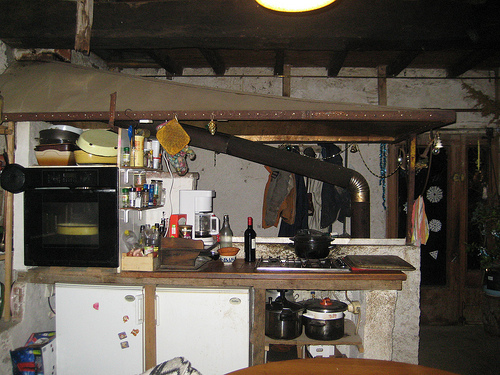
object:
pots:
[300, 313, 347, 341]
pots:
[74, 128, 118, 157]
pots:
[34, 143, 78, 167]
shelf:
[24, 122, 120, 267]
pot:
[287, 227, 335, 260]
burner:
[255, 254, 352, 274]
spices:
[121, 185, 133, 209]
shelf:
[120, 125, 165, 257]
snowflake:
[426, 185, 444, 203]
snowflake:
[428, 217, 442, 234]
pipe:
[114, 119, 370, 238]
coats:
[261, 145, 297, 230]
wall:
[159, 140, 386, 241]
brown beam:
[73, 0, 95, 55]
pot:
[193, 211, 220, 239]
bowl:
[219, 254, 237, 265]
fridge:
[54, 282, 144, 374]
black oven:
[23, 168, 118, 268]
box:
[167, 213, 187, 238]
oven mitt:
[155, 117, 192, 155]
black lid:
[288, 228, 335, 245]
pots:
[264, 294, 306, 340]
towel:
[409, 195, 430, 247]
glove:
[164, 142, 198, 177]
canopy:
[0, 56, 457, 142]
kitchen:
[0, 1, 492, 357]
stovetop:
[257, 253, 347, 269]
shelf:
[261, 288, 363, 358]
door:
[386, 133, 491, 326]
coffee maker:
[170, 188, 220, 242]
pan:
[56, 221, 100, 237]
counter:
[18, 256, 408, 289]